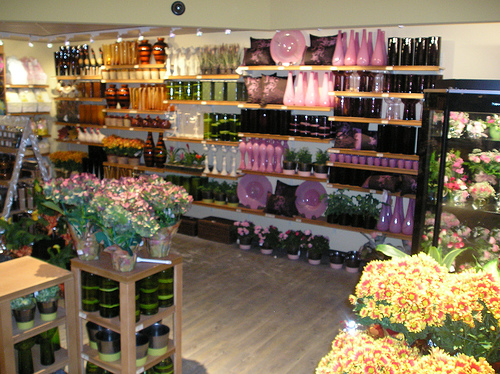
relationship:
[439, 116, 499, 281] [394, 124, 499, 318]
flowers visible in case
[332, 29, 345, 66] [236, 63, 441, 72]
vase on shelf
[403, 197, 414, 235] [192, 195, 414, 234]
lavender vase on shelf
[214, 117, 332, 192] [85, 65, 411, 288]
glassware on shelves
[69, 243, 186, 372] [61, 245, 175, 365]
table with shelves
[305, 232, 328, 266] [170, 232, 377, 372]
flower on floor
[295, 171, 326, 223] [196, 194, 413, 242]
plate on shelf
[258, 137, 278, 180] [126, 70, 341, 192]
vase on shelf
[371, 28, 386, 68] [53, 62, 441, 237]
vase on shelf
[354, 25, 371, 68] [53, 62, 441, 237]
vase on shelf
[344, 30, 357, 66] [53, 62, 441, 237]
lavender vase on shelf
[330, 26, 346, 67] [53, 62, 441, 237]
vase on shelf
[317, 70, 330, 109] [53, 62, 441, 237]
vase on shelf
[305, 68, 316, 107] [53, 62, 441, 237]
vase on shelf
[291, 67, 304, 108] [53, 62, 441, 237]
vase on shelf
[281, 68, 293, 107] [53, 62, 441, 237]
vase on shelf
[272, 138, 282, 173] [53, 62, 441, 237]
vase on shelf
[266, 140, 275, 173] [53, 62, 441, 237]
vase on shelf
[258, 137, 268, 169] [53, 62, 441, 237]
vase on shelf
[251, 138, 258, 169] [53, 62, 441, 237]
vase on shelf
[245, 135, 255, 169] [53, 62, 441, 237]
vase on shelf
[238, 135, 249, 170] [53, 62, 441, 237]
vase on shelf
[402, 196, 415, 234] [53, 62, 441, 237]
lavender vase on shelf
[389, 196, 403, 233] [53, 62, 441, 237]
lavender vase on shelf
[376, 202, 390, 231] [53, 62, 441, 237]
lavender vase on shelf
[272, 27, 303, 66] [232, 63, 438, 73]
plate on shelf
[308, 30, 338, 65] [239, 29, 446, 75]
pillow on shelf